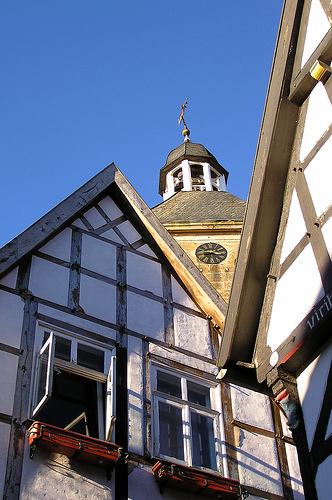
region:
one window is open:
[25, 313, 133, 469]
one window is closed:
[144, 349, 243, 496]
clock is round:
[193, 239, 228, 265]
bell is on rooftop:
[156, 142, 233, 194]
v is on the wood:
[304, 317, 315, 330]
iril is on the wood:
[313, 292, 331, 322]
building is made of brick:
[207, 266, 229, 279]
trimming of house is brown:
[235, 259, 253, 323]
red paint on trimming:
[278, 341, 304, 365]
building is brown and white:
[290, 191, 327, 256]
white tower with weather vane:
[155, 89, 233, 202]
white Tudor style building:
[3, 158, 331, 495]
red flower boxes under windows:
[24, 417, 253, 497]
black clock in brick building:
[193, 237, 230, 266]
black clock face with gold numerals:
[194, 236, 231, 267]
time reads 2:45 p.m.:
[197, 238, 228, 259]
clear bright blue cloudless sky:
[1, 0, 285, 245]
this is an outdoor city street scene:
[4, 0, 328, 495]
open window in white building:
[28, 319, 122, 443]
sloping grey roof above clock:
[153, 183, 262, 234]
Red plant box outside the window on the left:
[26, 419, 122, 467]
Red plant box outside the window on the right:
[151, 456, 244, 495]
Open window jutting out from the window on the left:
[28, 331, 60, 414]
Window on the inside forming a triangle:
[65, 409, 92, 435]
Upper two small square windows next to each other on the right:
[150, 363, 222, 406]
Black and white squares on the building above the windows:
[27, 222, 183, 341]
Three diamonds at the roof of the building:
[79, 193, 143, 246]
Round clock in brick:
[195, 241, 228, 264]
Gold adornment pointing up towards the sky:
[177, 95, 193, 135]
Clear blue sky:
[10, 12, 269, 90]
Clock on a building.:
[199, 239, 239, 263]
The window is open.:
[36, 342, 61, 376]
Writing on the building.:
[288, 308, 331, 320]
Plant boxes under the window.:
[164, 464, 216, 488]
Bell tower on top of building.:
[155, 170, 206, 183]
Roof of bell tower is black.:
[155, 147, 201, 156]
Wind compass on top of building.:
[166, 103, 193, 115]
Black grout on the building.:
[165, 297, 176, 325]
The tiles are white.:
[237, 398, 269, 414]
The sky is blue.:
[58, 97, 91, 102]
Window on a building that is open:
[25, 319, 112, 442]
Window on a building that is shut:
[148, 357, 219, 480]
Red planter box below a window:
[13, 410, 145, 478]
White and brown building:
[53, 224, 233, 359]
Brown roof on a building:
[6, 161, 233, 310]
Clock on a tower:
[181, 230, 247, 279]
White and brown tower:
[157, 143, 224, 211]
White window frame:
[141, 353, 225, 466]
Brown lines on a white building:
[287, 233, 331, 366]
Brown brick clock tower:
[165, 225, 259, 306]